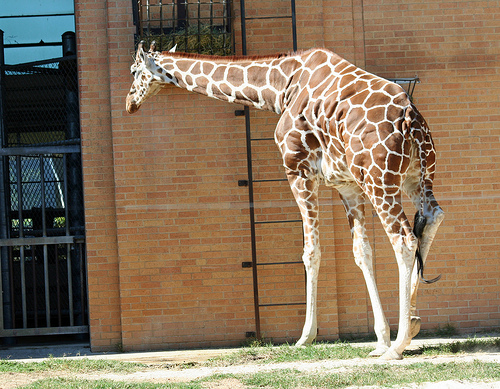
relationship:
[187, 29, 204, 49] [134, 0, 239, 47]
straw on window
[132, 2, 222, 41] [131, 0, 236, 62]
bars on windows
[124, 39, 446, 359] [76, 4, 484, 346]
giraffe on building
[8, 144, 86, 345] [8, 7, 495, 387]
barrier on giraffe pen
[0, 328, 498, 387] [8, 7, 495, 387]
grass in giraffe pen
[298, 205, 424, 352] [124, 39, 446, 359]
legs of giraffe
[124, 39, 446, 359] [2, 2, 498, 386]
giraffe in pen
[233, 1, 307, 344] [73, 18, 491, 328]
ladder on side of building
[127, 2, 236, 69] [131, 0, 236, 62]
metal cover over windows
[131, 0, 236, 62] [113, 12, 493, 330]
windows in wall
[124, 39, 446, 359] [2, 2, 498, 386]
giraffe in a pen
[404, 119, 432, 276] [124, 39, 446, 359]
tail of giraffe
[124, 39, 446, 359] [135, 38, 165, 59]
giraffe with horns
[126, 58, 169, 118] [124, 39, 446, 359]
head of giraffe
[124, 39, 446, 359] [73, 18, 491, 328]
giraffe in front of building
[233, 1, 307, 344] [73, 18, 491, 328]
ladder attached to building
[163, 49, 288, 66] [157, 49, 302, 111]
hair on neck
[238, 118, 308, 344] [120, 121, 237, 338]
ladder against wall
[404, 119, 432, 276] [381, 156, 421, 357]
tail between legs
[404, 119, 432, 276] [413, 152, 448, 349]
tail between legs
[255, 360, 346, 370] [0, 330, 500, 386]
patch on ground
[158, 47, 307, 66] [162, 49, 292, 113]
mane along neck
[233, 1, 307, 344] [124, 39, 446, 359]
ladder behind giraffe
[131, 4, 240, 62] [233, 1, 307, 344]
windows next to ladder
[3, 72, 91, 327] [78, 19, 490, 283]
fence on building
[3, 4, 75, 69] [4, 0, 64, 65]
sky void clouds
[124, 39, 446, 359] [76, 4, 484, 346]
giraffe next to building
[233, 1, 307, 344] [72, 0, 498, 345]
ladder next to wall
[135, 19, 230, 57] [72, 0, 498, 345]
troth on wall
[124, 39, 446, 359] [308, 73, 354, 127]
giraffe has spots